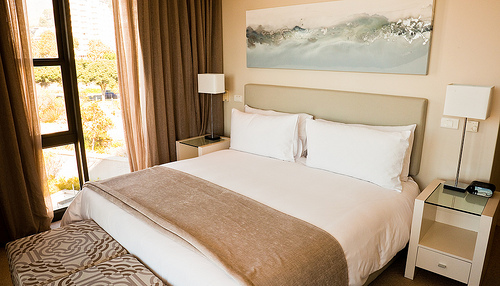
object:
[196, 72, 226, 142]
lamp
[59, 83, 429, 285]
bed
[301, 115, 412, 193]
pillows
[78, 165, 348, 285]
bedspread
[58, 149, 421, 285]
cover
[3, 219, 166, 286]
seat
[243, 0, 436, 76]
painting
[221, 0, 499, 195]
wall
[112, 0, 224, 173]
coverings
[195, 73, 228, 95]
lamp shade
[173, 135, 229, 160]
night stand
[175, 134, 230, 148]
table top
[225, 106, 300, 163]
pillow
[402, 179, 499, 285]
nightstand